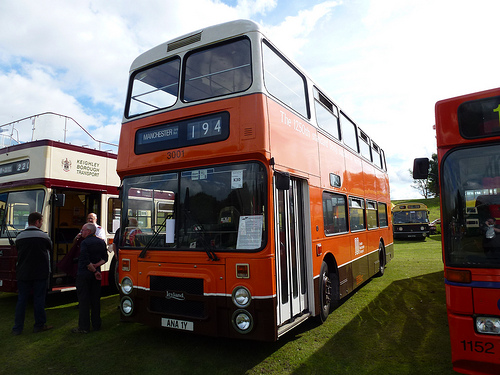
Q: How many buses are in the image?
A: Four.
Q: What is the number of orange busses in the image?
A: One.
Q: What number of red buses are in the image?
A: One.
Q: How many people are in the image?
A: Three.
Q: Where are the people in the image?
A: On the left.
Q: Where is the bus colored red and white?
A: On the left.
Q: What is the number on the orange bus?
A: 194.